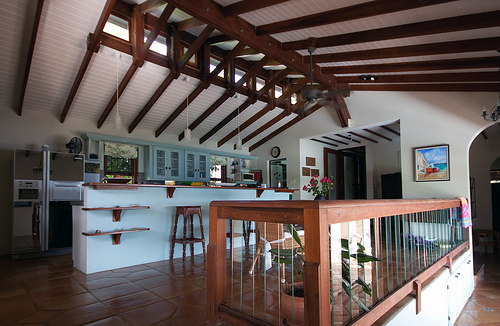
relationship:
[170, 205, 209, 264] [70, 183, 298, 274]
stool in front of bar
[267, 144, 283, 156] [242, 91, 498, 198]
clock on wall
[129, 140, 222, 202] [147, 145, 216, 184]
glass on cupboard doors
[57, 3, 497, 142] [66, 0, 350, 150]
beams on ceiling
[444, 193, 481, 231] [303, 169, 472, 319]
towel draped over divider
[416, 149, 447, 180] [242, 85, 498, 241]
painting on wall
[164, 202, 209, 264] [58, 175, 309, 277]
stool by bar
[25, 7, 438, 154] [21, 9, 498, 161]
wood trusses on ceiling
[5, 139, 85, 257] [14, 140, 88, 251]
freezer behind bar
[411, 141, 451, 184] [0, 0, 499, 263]
painting on wall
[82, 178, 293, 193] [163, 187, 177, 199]
bar top supported by wedge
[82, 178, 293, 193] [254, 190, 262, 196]
bar top supported by wedge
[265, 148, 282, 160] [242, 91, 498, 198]
clock on wall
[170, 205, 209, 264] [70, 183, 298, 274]
stool by bar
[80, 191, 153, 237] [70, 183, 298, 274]
shelves on bar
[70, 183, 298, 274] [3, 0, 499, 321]
bar in kitchen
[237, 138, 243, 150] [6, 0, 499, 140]
lights hanging from ceiling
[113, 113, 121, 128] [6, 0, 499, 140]
light hanging from ceiling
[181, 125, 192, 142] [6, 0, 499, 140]
light hanging from ceiling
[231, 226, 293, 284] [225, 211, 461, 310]
railing with bars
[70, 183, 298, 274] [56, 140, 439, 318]
bar in kitchen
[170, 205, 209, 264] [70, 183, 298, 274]
stool at bar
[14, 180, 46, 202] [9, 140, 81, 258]
ice maker on refrigerator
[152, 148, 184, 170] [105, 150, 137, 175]
cabinets between windows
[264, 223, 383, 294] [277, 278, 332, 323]
plant in pot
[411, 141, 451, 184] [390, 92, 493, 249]
painting on wall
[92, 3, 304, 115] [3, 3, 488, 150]
lights with frames